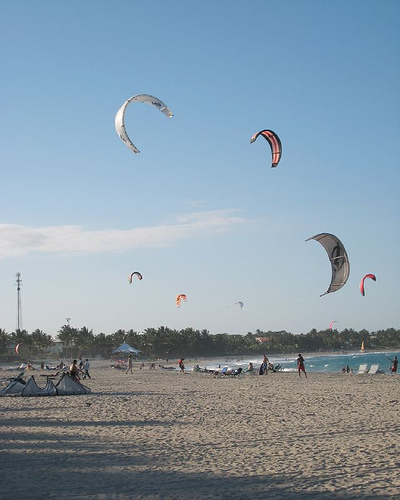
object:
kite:
[304, 232, 349, 297]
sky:
[84, 0, 149, 44]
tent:
[111, 341, 143, 362]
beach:
[0, 369, 400, 498]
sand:
[6, 400, 387, 498]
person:
[125, 355, 133, 374]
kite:
[360, 274, 376, 296]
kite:
[329, 320, 336, 331]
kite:
[15, 343, 22, 355]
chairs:
[368, 364, 378, 374]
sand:
[209, 371, 400, 453]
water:
[312, 359, 341, 369]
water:
[340, 352, 395, 369]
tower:
[14, 271, 23, 328]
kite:
[176, 293, 186, 307]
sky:
[0, 0, 112, 99]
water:
[218, 349, 398, 371]